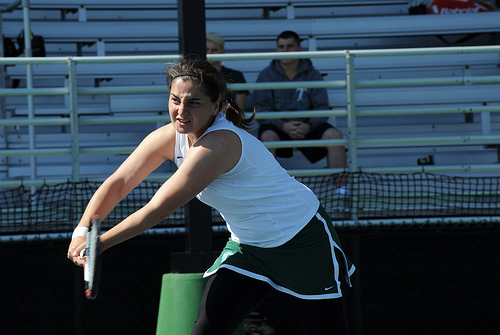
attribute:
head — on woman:
[168, 62, 224, 133]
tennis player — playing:
[69, 57, 356, 334]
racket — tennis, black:
[80, 217, 99, 299]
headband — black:
[172, 71, 199, 76]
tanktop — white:
[174, 112, 319, 247]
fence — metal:
[0, 46, 499, 243]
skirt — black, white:
[202, 209, 358, 301]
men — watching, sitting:
[208, 31, 355, 203]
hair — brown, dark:
[169, 60, 257, 126]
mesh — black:
[3, 171, 500, 242]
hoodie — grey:
[249, 54, 330, 127]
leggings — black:
[192, 276, 347, 333]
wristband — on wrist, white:
[71, 224, 88, 238]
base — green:
[154, 275, 207, 335]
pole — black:
[169, 1, 220, 271]